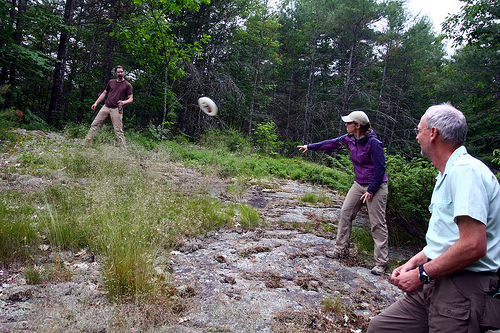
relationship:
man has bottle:
[60, 51, 142, 152] [114, 92, 129, 117]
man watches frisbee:
[60, 51, 142, 152] [194, 75, 227, 122]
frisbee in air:
[194, 75, 227, 122] [134, 38, 289, 172]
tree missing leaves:
[147, 20, 185, 152] [116, 11, 212, 75]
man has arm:
[60, 51, 142, 152] [127, 75, 138, 115]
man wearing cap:
[60, 51, 142, 152] [340, 111, 371, 128]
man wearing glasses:
[355, 99, 499, 285] [404, 115, 430, 136]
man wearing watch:
[355, 99, 499, 285] [416, 254, 441, 283]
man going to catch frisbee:
[60, 51, 142, 152] [194, 75, 227, 122]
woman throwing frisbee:
[294, 89, 406, 264] [194, 75, 227, 122]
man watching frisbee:
[60, 51, 142, 152] [194, 75, 227, 122]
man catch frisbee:
[60, 51, 142, 152] [194, 75, 227, 122]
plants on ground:
[83, 175, 252, 252] [127, 177, 293, 315]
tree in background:
[147, 20, 185, 152] [56, 28, 424, 185]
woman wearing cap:
[294, 89, 406, 264] [331, 104, 370, 130]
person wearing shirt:
[60, 51, 142, 152] [87, 77, 145, 112]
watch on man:
[416, 254, 441, 283] [355, 99, 499, 285]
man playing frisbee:
[364, 102, 500, 333] [194, 75, 227, 122]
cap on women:
[331, 104, 370, 130] [294, 89, 406, 264]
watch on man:
[416, 254, 441, 283] [60, 51, 142, 152]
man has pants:
[60, 51, 142, 152] [71, 101, 132, 160]